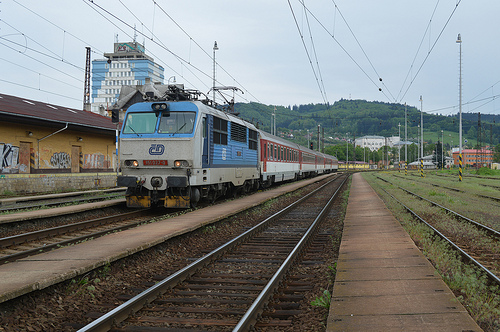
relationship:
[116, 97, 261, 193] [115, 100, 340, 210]
front car on train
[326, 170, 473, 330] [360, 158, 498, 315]
pathway near grass